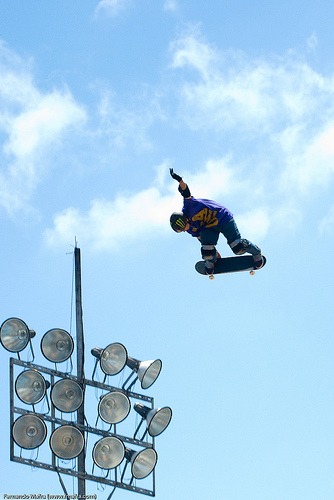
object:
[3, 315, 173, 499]
rows of light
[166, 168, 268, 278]
skateboarder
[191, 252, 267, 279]
trick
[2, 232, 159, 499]
wires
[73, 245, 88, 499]
pole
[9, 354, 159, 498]
metal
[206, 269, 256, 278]
wheels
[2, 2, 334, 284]
clouds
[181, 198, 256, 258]
outift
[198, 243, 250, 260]
knee pads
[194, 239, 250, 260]
joints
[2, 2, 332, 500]
air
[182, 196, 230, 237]
blue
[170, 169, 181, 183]
gloves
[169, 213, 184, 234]
helmet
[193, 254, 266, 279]
skateboard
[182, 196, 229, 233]
shirt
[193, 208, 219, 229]
yellow writing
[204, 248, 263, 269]
shoes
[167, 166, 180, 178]
glove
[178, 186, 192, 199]
armband